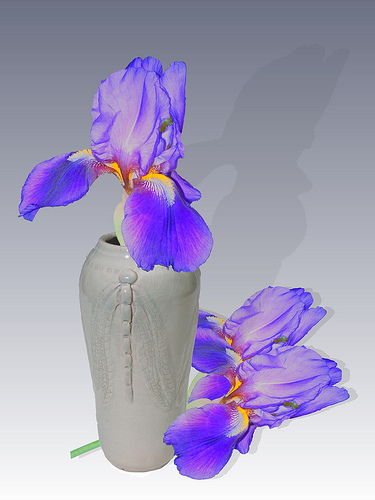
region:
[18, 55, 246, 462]
flowers in a vase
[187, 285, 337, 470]
flowers outside the vase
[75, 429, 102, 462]
stem on the flower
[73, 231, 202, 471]
vase with pattern on it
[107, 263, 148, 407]
protrusion on outside of vase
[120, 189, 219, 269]
petal on the flower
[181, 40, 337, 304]
shadow from the flower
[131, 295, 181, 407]
design on the vase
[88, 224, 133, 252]
edge of the vase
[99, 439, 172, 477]
base of the vase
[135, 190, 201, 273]
purple petal on a flower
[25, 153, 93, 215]
purple petal on a flower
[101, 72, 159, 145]
purple petal on a flower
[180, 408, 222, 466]
purple petal on a flower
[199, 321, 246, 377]
purple petal on a flower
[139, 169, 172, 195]
yellow part on a petal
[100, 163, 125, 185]
yellow part on a petal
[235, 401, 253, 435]
yellow part on a petal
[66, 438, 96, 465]
green bottom of a stem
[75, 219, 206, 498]
grey vase holding irises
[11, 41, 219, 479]
This is a flower vase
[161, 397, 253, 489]
This is a flower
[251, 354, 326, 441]
This is a flower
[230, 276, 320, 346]
This is a flower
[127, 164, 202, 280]
This is a flower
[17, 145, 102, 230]
This is a flower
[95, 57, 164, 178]
This is a flower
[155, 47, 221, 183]
This is a flower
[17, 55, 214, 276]
Purple flowers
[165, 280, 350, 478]
purple and yellow petals on the ground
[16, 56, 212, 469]
purple flowers in vase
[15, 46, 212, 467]
flowers displayed in a vase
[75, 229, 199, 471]
a gray vase with designs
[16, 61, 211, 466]
small flowers in a vase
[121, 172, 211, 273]
a yellow and purple petal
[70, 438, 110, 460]
a green flower stem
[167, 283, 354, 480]
flowers laying down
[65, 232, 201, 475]
a dragon fly on a vase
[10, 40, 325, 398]
a beautiful 3-d painting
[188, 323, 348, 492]
an iris drawn on paper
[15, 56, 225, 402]
a vase with a purple iris in it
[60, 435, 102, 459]
green stem of a flower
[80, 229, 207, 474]
a ceramic vase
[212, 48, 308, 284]
shadow of a flower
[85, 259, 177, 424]
detail on the vase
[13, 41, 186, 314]
a flower that is in a vase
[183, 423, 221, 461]
shades of purple on a petal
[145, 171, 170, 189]
yellow center of a flower